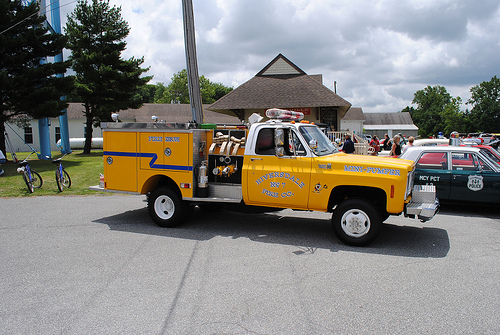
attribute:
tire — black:
[145, 184, 188, 228]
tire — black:
[329, 197, 382, 245]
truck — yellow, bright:
[99, 106, 440, 246]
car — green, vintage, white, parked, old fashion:
[391, 146, 499, 211]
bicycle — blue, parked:
[50, 154, 71, 194]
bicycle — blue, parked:
[13, 148, 43, 195]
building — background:
[363, 110, 419, 143]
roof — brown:
[362, 111, 413, 124]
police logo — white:
[465, 173, 485, 192]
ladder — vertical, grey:
[180, 1, 205, 126]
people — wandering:
[335, 129, 417, 158]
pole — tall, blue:
[50, 1, 76, 156]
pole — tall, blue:
[30, 0, 53, 157]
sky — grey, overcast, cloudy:
[13, 1, 499, 113]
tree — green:
[59, 0, 155, 158]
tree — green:
[1, 0, 75, 164]